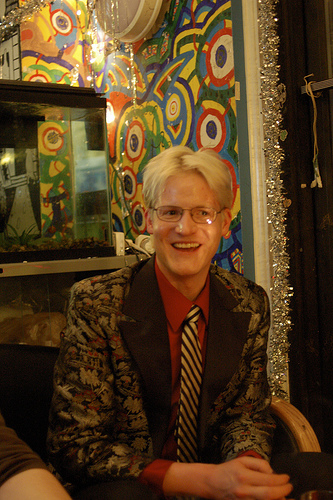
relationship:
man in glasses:
[50, 146, 293, 499] [146, 201, 228, 221]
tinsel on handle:
[303, 72, 322, 189] [298, 76, 332, 96]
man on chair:
[50, 146, 293, 499] [270, 395, 323, 500]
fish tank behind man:
[2, 78, 117, 258] [50, 146, 293, 499]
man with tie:
[50, 146, 293, 499] [175, 304, 202, 462]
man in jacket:
[50, 146, 293, 499] [47, 253, 275, 499]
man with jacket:
[50, 146, 293, 499] [47, 253, 275, 499]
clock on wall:
[94, 1, 174, 44] [20, 2, 244, 276]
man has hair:
[50, 146, 293, 499] [141, 144, 232, 222]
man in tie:
[50, 146, 293, 499] [175, 304, 202, 462]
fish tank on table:
[2, 78, 117, 258] [2, 256, 156, 276]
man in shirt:
[50, 146, 293, 499] [143, 260, 261, 500]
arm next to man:
[1, 413, 70, 499] [50, 146, 293, 499]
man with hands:
[50, 146, 293, 499] [168, 455, 292, 499]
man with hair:
[50, 146, 293, 499] [141, 144, 232, 222]